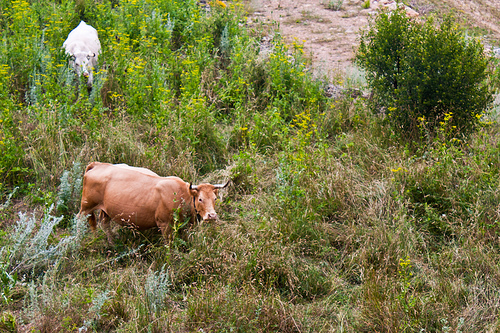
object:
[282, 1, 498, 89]
ground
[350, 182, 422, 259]
patch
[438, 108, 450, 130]
yellow plant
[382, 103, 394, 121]
yellow plant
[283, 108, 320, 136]
yellow plant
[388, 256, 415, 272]
yellow plant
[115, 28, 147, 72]
yellow plant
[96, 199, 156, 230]
belly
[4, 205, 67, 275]
plants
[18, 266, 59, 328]
plants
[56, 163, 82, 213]
plants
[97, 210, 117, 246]
leg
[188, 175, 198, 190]
horn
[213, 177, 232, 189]
horn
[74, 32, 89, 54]
white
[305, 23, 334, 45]
rocks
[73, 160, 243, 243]
cow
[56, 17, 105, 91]
white cow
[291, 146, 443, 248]
grass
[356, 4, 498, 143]
bush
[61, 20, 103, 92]
cow